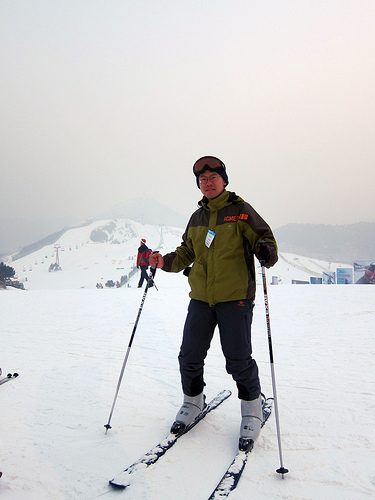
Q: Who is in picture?
A: A man.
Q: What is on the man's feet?
A: Skis.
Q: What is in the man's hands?
A: Poles.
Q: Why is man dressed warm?
A: It is cold.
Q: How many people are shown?
A: Two.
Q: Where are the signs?
A: On the right.